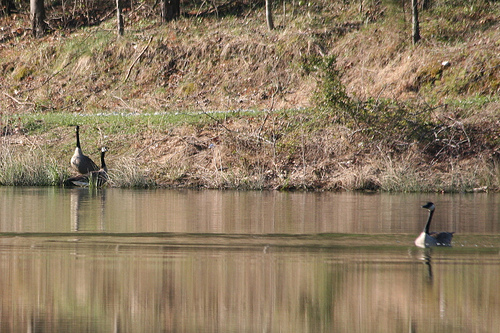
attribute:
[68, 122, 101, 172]
goose — larger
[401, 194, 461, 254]
bird — one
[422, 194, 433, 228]
head — bird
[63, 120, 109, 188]
birds — feathered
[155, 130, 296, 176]
grass — brown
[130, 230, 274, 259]
ripples — some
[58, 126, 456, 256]
birds — some, three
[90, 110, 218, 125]
grass — green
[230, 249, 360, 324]
reflection — watery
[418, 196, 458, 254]
duck — one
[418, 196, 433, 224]
head — one, duck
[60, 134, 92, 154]
neck — duck, long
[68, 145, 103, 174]
body — duck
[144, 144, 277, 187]
brush — brown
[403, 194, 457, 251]
bird — floating